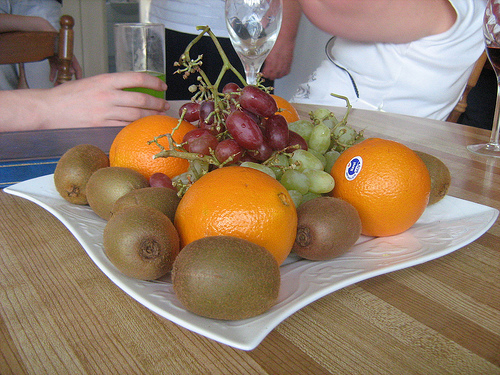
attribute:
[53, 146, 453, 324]
kiwi — fruit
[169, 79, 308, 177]
grape — red,  rippen maroon, green 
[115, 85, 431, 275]
orange — dimpled skin, skin, label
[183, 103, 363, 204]
grape — green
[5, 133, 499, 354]
plate — white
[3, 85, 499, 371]
table — wood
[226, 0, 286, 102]
glass — empty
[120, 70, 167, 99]
liquid — green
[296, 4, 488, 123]
shirt — white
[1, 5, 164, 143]
person — drinking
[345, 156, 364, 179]
tag — white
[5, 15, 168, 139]
arm —  back 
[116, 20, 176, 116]
glass —  drinking 